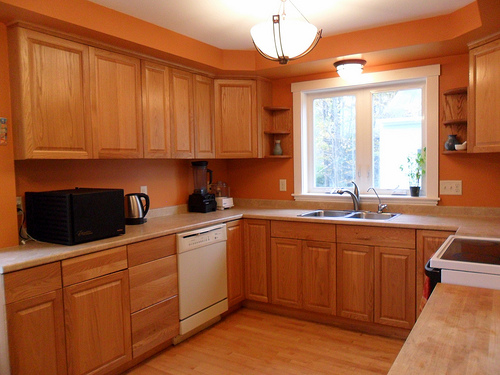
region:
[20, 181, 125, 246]
A black microwave on kitchen counter.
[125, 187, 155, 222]
A coffee pot on kitchen counter.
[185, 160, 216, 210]
A blender on kitchen counter.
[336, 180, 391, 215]
The kitchen faucet.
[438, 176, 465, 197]
Electrical outlet on kitchen wall.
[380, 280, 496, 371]
A beige kitchen counter.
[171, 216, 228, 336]
Dishwasher under kitchen counter.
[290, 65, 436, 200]
Window over kitchen sink.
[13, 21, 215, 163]
Five cabinets in kitchen.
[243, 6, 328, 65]
Light hanging from kitchen ceiling.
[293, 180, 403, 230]
Silver kitchen sink by window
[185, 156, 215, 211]
Black and clear blender next to food processor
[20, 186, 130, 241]
Black microwave on counter top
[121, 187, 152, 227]
Silver coffee pot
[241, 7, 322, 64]
Hanging kitchen light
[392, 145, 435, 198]
Potted plant in window sill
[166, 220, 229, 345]
White dish washer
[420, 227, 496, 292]
Stove top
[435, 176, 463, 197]
Light switch on wall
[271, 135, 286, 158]
Vase on shelf in kitchen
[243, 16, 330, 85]
white light in kitchen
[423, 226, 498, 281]
white appliance with black top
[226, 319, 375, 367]
light brown wood floor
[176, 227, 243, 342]
white dish washer with handle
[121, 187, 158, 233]
silver coffee pot with black handle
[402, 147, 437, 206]
black pot with green plant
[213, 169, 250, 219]
blender with white base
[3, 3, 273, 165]
light brown kitchen cabinets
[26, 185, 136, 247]
black microwave on counter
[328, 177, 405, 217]
several silver faucets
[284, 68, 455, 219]
large over the sink kitchen window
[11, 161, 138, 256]
black microwave on countertop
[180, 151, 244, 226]
small kitchen appliances sitting on counter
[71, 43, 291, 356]
beautiful golden oak cabinetry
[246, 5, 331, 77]
modern pendant kitchen light fixture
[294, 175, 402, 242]
stainless steel sink with a hot water dispenser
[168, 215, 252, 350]
white under the counter dishwasher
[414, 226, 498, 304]
white, flat cooktop stove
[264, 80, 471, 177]
decorative shelves flanking the window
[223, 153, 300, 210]
bright orange painted walls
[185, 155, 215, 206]
Black blender on counter top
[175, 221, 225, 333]
White dishwasher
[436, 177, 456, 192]
Light switches on wall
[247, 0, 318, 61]
Light fixture on ceiling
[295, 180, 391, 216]
Metal kitchen sink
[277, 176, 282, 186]
White power outlet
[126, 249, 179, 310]
Brown wooden kitchen drawer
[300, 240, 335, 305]
Brown wooden cabinet door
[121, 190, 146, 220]
Metallic coffee pot on counter top